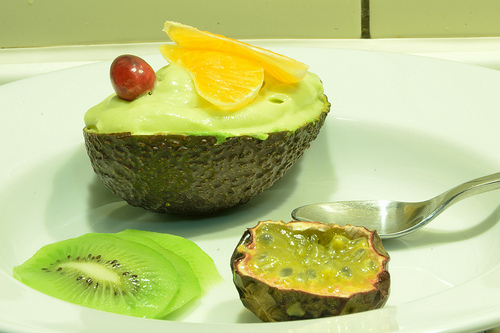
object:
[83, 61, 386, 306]
fruits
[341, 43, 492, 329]
plate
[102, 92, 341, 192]
avocado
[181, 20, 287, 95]
fruit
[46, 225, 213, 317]
kiwi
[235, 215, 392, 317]
fruit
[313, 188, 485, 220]
spoon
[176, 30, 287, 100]
orange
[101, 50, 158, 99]
grape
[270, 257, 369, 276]
seeds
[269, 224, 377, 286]
center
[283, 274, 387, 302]
filling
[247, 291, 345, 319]
skin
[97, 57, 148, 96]
olive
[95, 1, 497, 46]
wall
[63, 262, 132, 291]
seeds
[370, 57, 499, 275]
bowl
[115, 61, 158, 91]
cherry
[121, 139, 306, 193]
skin